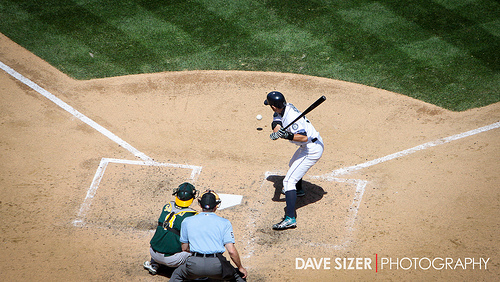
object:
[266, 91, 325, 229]
man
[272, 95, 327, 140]
bat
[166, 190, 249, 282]
umpire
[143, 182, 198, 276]
player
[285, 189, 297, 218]
sock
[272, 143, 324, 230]
leg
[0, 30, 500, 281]
sand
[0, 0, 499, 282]
field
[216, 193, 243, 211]
home plate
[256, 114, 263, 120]
baseball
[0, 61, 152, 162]
line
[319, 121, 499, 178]
line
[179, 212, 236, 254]
shirt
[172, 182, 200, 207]
hat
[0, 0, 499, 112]
grass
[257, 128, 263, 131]
shadow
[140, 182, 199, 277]
uniform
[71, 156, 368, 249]
batter's box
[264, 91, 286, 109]
helmet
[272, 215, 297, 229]
shoe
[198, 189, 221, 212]
protective gear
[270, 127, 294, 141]
gloves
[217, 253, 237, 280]
ball pouch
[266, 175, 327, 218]
shadow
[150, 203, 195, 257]
shirt